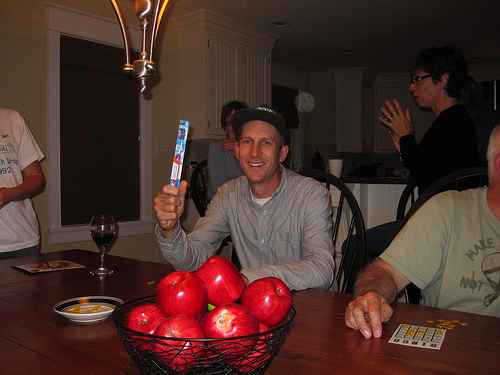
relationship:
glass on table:
[73, 204, 155, 275] [47, 242, 349, 371]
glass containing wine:
[82, 216, 120, 281] [90, 229, 117, 248]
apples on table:
[151, 246, 281, 337] [260, 278, 379, 368]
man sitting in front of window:
[150, 101, 339, 292] [58, 36, 141, 225]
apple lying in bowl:
[153, 269, 207, 318] [109, 290, 298, 372]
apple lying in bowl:
[190, 251, 244, 304] [109, 290, 298, 372]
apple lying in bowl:
[239, 274, 293, 325] [109, 290, 298, 372]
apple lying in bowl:
[123, 301, 163, 351] [109, 290, 298, 372]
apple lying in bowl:
[150, 313, 204, 370] [109, 290, 298, 372]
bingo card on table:
[384, 318, 449, 354] [6, 306, 486, 367]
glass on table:
[84, 206, 122, 281] [20, 248, 144, 292]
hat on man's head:
[222, 101, 306, 143] [191, 96, 328, 220]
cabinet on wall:
[197, 20, 275, 163] [113, 20, 258, 205]